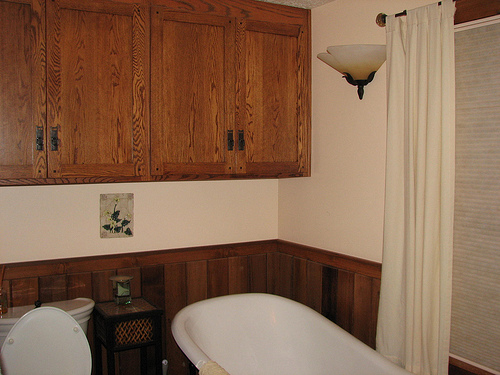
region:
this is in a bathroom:
[26, 30, 480, 340]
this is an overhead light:
[277, 29, 449, 134]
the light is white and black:
[306, 34, 394, 103]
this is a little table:
[87, 278, 184, 363]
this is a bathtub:
[185, 290, 317, 374]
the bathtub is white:
[204, 290, 348, 367]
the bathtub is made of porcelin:
[195, 307, 319, 374]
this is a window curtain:
[385, 141, 495, 305]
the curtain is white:
[365, 172, 498, 236]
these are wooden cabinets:
[15, 22, 289, 201]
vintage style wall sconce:
[316, 38, 387, 104]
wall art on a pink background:
[77, 185, 174, 248]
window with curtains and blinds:
[374, 5, 499, 363]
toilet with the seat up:
[1, 271, 105, 369]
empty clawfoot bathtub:
[171, 255, 430, 374]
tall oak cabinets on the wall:
[3, 0, 315, 190]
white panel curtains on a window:
[378, 8, 459, 373]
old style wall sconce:
[316, 35, 387, 101]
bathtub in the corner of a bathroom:
[151, 198, 411, 373]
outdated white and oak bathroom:
[1, 0, 492, 374]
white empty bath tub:
[168, 278, 410, 373]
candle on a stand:
[108, 269, 137, 310]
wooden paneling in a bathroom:
[157, 267, 234, 297]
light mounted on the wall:
[311, 34, 392, 113]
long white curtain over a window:
[380, 28, 457, 374]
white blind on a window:
[464, 119, 494, 239]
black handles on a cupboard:
[220, 123, 252, 155]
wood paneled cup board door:
[155, 8, 232, 170]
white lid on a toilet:
[5, 299, 88, 374]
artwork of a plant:
[93, 191, 144, 246]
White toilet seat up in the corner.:
[0, 303, 91, 371]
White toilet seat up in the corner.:
[156, 343, 178, 373]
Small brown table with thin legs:
[95, 295, 166, 374]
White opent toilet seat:
[1, 305, 91, 373]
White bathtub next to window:
[168, 291, 409, 373]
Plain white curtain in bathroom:
[374, 133, 456, 373]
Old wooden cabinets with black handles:
[2, 133, 311, 188]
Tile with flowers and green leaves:
[96, 193, 136, 240]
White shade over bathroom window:
[447, 134, 499, 373]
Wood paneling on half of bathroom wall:
[1, 237, 388, 374]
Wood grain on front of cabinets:
[131, 135, 146, 180]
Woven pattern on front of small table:
[110, 313, 163, 348]